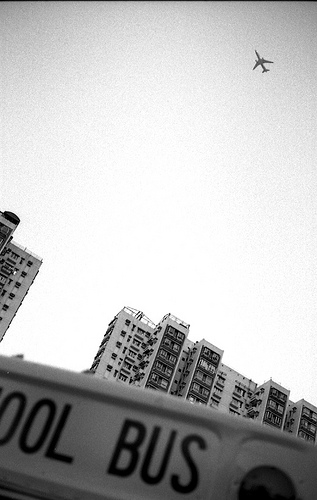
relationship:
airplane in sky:
[251, 47, 274, 73] [185, 4, 314, 131]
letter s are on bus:
[171, 433, 207, 494] [0, 352, 316, 498]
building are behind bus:
[89, 296, 306, 432] [6, 364, 316, 491]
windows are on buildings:
[89, 319, 315, 442] [89, 305, 315, 442]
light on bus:
[234, 461, 296, 500] [95, 396, 232, 493]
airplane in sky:
[251, 47, 274, 73] [191, 24, 307, 114]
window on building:
[25, 260, 32, 269] [1, 206, 48, 354]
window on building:
[166, 324, 175, 337] [89, 304, 316, 441]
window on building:
[197, 360, 208, 372] [89, 304, 316, 441]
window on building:
[272, 389, 277, 400] [89, 304, 316, 441]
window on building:
[151, 360, 166, 370] [89, 304, 316, 441]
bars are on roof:
[120, 306, 153, 318] [122, 306, 153, 329]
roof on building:
[122, 306, 153, 329] [87, 304, 154, 385]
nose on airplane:
[252, 46, 263, 56] [251, 47, 274, 73]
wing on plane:
[261, 56, 273, 65] [252, 48, 274, 72]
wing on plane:
[261, 56, 273, 65] [252, 51, 270, 75]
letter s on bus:
[171, 433, 207, 494] [0, 352, 316, 498]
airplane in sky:
[251, 47, 274, 73] [3, 4, 315, 292]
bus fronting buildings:
[0, 352, 316, 498] [5, 210, 316, 433]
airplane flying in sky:
[251, 47, 274, 73] [0, 0, 315, 373]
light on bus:
[234, 461, 293, 493] [15, 356, 216, 495]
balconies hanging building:
[246, 385, 267, 418] [89, 296, 306, 432]